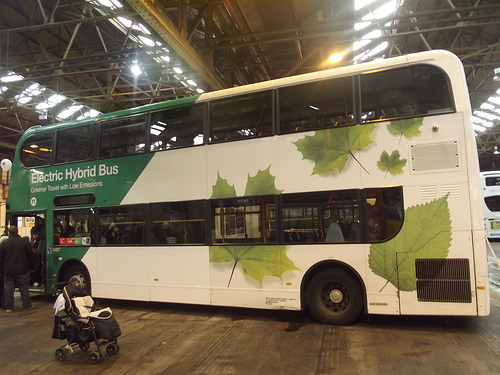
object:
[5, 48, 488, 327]
bus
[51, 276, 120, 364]
stroller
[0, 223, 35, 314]
man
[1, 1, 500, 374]
structure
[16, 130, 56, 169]
window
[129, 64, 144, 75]
light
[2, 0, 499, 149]
ceiling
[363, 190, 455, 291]
leaf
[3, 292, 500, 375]
floor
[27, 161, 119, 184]
decal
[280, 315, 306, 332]
fluid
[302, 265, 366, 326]
tire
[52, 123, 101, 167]
window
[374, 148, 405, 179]
leaf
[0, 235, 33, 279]
black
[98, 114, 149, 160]
window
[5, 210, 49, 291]
door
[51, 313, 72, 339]
bags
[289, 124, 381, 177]
leaf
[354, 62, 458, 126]
windows